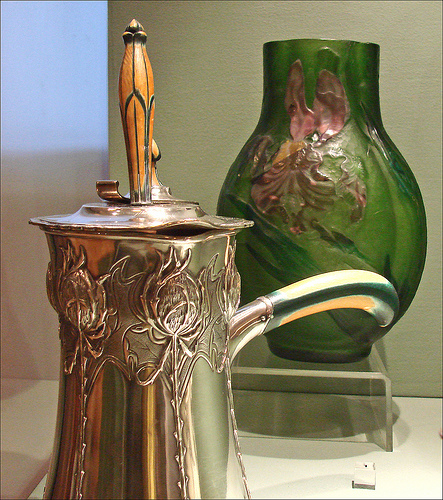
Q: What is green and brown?
A: Vase.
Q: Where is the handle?
A: On canister.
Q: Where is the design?
A: On vase.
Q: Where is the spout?
A: On canister.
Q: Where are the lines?
A: On vase.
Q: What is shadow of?
A: Vase.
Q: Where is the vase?
A: By wall.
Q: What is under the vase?
A: Shadow.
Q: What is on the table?
A: Metal container.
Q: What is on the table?
A: Designed container.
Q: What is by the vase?
A: Container lid.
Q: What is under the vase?
A: Clear shelf.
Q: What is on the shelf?
A: See through vase.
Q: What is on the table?
A: Light reflecting.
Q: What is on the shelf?
A: Flower on vase.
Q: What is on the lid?
A: Wooden handle.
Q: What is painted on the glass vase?
A: Flowers.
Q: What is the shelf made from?
A: Plastic.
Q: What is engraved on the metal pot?
A: Flowers.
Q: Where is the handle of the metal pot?
A: On the lid.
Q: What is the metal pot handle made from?
A: Wood.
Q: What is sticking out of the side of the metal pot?
A: A spout.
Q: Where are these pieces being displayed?
A: In a gallery.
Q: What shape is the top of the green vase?
A: Circular.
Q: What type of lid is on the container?
A: Bronze.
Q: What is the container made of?
A: Metal.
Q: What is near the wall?
A: A vase.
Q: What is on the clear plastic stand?
A: A green vase.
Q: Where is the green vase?
A: On the pedestal.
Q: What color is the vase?
A: Green.